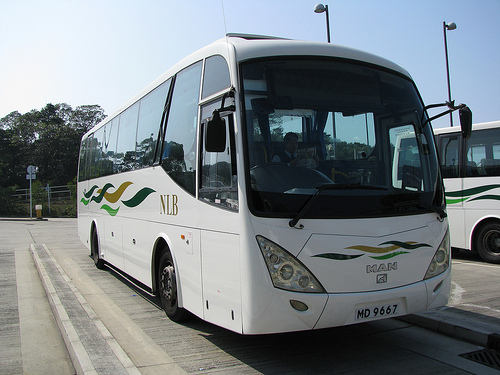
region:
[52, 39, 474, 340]
a charter bus parked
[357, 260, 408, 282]
bus manufacturer's name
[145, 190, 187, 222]
bus owner's logo on the side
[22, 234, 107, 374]
a cement curb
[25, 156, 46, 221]
traffic sign in a street corner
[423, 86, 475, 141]
driver's side mirror of bus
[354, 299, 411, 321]
front license plate on a bus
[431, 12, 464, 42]
a light on a lamp post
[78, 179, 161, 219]
detailing on th side of a bus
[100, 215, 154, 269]
side storage bays on a bus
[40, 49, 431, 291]
large white and black bus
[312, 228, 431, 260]
designs on front of bus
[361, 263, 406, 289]
silver logo on front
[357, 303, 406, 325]
licence plate on bottom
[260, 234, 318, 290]
front lights on bus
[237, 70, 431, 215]
front window on bus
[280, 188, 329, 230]
window wiper on bus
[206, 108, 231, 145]
side view mirror on bus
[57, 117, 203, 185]
side windows on bus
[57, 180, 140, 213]
designs on side of bus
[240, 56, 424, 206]
Large window on a bus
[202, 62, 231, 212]
Large window on a bus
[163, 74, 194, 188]
Large window on a bus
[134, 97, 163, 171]
Large window on a bus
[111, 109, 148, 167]
Large window on a bus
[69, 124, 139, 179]
Large window on a bus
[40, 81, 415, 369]
Large white bus on pavement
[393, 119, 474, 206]
Large white bus on pavement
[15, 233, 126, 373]
Small stripes on pavement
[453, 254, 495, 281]
Small stripes on pavement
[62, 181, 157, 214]
the decorative design on the side of the bus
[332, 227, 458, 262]
decorative design on the front of the bus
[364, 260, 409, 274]
the word man on the front of the bus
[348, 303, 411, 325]
the license plate on the front of the bus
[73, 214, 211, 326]
the wheels on the bus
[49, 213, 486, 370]
the parking spot the bus is parked in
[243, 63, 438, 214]
the front windshield of the bus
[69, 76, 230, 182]
side windows on the bus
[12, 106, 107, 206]
the trees in the distance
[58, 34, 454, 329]
the big white bus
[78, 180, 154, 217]
white bus with designs on it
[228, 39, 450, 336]
Front of white bus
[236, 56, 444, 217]
Front windshield of the white bus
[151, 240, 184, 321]
Right front wheel of the white bus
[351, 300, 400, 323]
License plate on the front of the bus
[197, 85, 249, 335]
Front passenger entrance/exit door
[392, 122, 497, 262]
Another white bus with designs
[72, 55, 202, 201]
Passenger windows on the right side of the bus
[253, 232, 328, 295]
Headlight on the right side of the bus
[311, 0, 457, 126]
Light poles in the distance